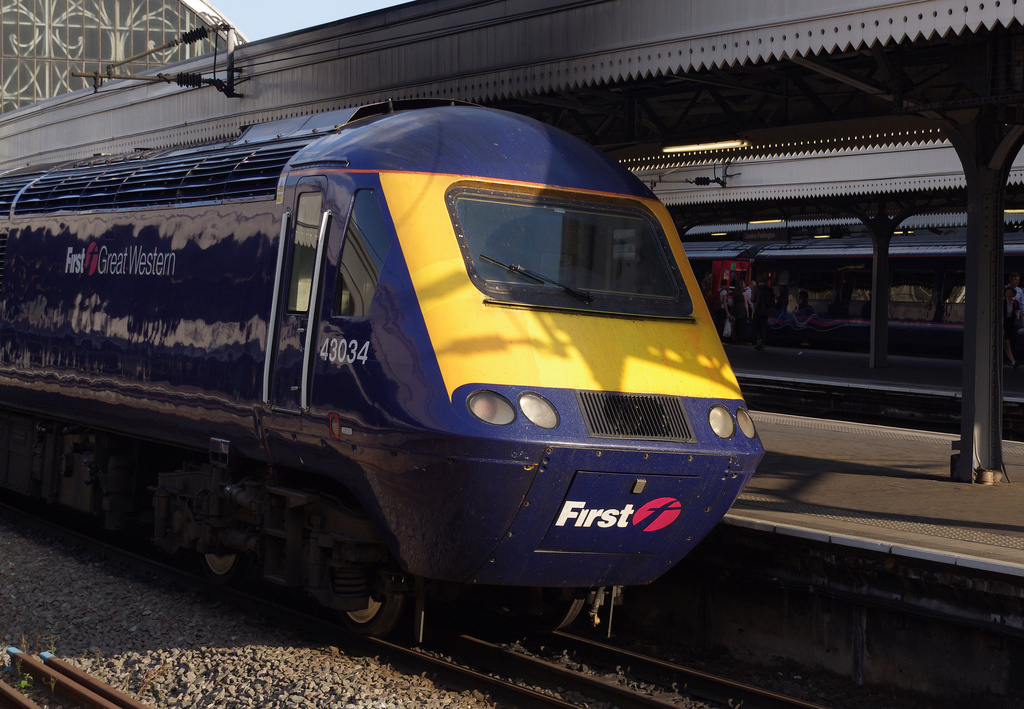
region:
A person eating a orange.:
[544, 295, 778, 499]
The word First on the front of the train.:
[547, 490, 643, 545]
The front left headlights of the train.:
[459, 385, 558, 428]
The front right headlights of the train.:
[710, 402, 753, 442]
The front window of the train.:
[447, 183, 698, 326]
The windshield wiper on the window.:
[485, 244, 590, 305]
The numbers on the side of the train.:
[310, 335, 374, 361]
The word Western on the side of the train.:
[128, 238, 183, 281]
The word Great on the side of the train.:
[99, 238, 134, 281]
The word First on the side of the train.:
[58, 238, 98, 267]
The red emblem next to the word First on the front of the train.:
[634, 496, 677, 534]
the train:
[247, 112, 723, 571]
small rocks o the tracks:
[194, 662, 306, 701]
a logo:
[552, 481, 680, 539]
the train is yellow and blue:
[392, 162, 712, 454]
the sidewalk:
[792, 446, 904, 533]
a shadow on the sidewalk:
[779, 437, 901, 526]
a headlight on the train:
[509, 384, 557, 430]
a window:
[457, 194, 669, 311]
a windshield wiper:
[479, 247, 572, 286]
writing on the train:
[54, 238, 179, 274]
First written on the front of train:
[479, 459, 756, 634]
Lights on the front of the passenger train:
[401, 346, 842, 558]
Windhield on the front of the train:
[386, 131, 794, 445]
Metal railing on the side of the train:
[245, 166, 423, 496]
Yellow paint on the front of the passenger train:
[318, 138, 868, 550]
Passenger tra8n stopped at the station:
[66, 20, 965, 632]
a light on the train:
[512, 363, 573, 463]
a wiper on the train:
[488, 238, 571, 302]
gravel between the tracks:
[111, 579, 204, 698]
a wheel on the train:
[313, 519, 413, 646]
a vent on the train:
[576, 381, 698, 446]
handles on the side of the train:
[291, 277, 324, 372]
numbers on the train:
[318, 321, 383, 389]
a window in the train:
[446, 192, 614, 259]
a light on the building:
[649, 113, 789, 175]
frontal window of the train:
[450, 186, 692, 335]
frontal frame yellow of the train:
[377, 169, 738, 391]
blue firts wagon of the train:
[36, 178, 733, 570]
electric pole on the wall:
[28, 22, 248, 95]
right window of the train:
[283, 177, 321, 315]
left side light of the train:
[456, 375, 556, 440]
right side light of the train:
[708, 390, 762, 449]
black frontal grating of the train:
[576, 392, 698, 446]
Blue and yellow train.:
[23, 78, 814, 660]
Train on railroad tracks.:
[11, 103, 825, 704]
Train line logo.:
[54, 231, 184, 280]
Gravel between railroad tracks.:
[7, 614, 312, 701]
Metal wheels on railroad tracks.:
[161, 430, 428, 664]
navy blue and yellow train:
[10, 119, 792, 673]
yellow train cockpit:
[355, 168, 811, 611]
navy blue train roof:
[10, 89, 678, 222]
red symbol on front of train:
[627, 473, 716, 581]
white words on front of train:
[535, 467, 638, 550]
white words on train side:
[35, 215, 220, 304]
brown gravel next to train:
[13, 535, 441, 706]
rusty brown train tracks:
[1, 617, 148, 703]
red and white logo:
[514, 480, 707, 588]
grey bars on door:
[260, 178, 321, 382]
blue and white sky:
[90, 0, 382, 143]